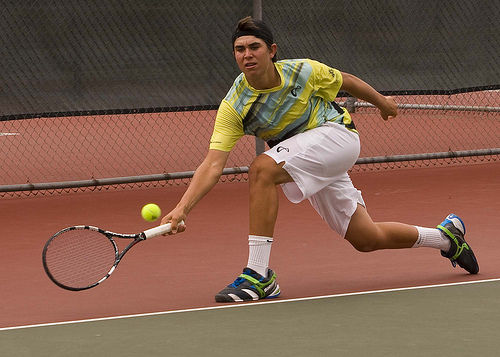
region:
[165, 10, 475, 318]
this is a person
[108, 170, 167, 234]
this is a ball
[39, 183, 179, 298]
this is a racket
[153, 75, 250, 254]
this is a hand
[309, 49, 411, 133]
this is a hand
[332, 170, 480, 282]
this is a leg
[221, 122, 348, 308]
this is a leg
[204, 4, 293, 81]
this is a head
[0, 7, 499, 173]
this is a net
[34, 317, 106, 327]
a white line on the net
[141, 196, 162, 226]
The tennis ball is yellow.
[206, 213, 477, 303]
The feet are wearing sneakers.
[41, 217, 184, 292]
A tennis racquet is partly white.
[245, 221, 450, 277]
A man is wearing white socks.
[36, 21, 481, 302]
A man is playing tennis.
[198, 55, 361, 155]
A smn is wearing a short sleeved shirt.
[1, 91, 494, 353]
The tennis court is red and green with a white line.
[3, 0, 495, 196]
Fencing is behind the man.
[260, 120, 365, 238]
A man is wearing white shorts.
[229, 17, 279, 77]
A head with a black headband.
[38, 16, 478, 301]
man playing tennis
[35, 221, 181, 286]
tennis racket with white handle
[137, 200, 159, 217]
yellow tennis ball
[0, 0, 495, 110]
black tarp covering fence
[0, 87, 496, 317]
red part of the tennis courts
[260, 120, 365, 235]
white shorts worn by tennis player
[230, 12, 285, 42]
cap worn by tennis player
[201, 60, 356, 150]
shirt worn by tennis player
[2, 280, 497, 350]
green part of the tennis court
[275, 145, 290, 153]
black logo on the shorts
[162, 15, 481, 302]
human playing tennis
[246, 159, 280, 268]
muscles of leg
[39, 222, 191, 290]
racquet for tennis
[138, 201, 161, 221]
tennis ball for game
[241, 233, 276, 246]
nike brand tube socks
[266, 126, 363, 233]
white shorts for tennis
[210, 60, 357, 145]
yellow shirt with blue and black design for tennis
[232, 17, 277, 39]
backwards cap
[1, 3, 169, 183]
fence to surround tennis court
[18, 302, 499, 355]
tennis court for tennis game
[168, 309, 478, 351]
The ground is made of concrete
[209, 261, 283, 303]
The shoe of the tennis player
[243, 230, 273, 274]
The man has on a white sock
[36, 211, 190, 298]
The man is holding a tennis racket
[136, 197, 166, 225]
The ball is in the air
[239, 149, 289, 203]
The knee of the player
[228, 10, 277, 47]
The man has on a black cap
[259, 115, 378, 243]
The man has on white shorts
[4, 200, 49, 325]
The ground is the color red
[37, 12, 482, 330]
The man is hitting the tennis ball